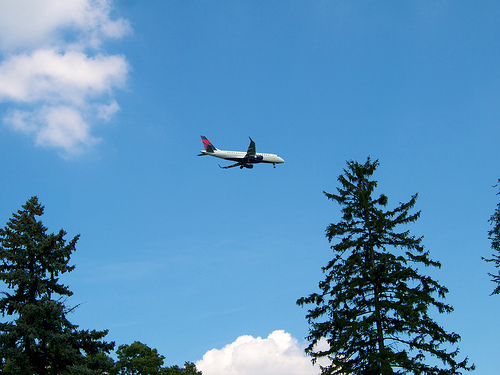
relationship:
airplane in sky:
[196, 136, 285, 173] [1, 2, 499, 373]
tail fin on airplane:
[200, 136, 214, 152] [196, 136, 285, 173]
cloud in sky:
[193, 327, 349, 374] [1, 2, 499, 373]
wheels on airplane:
[239, 156, 252, 172] [196, 136, 285, 173]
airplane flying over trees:
[196, 136, 285, 173] [0, 162, 468, 372]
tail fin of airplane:
[200, 136, 214, 152] [196, 136, 285, 173]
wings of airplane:
[218, 137, 259, 170] [196, 136, 285, 173]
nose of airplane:
[273, 153, 286, 166] [196, 136, 285, 173]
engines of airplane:
[239, 153, 263, 172] [196, 136, 285, 173]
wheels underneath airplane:
[239, 156, 252, 172] [196, 136, 285, 173]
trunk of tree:
[357, 192, 391, 373] [294, 157, 472, 374]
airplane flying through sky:
[196, 136, 285, 173] [1, 2, 499, 373]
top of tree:
[325, 157, 419, 227] [294, 157, 472, 374]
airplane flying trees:
[196, 136, 285, 173] [0, 162, 468, 372]